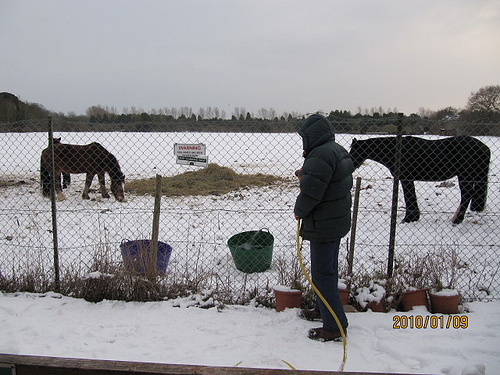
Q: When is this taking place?
A: Daytime.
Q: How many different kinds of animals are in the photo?
A: One.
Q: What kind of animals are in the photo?
A: Horse.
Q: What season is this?
A: Winter.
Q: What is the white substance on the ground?
A: Snow.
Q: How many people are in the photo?
A: One.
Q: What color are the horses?
A: Brown and black.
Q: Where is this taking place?
A: Farm.